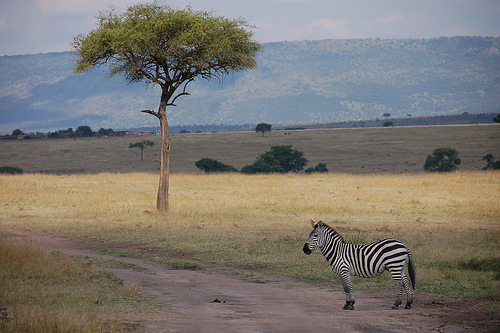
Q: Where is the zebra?
A: Road.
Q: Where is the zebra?
A: Plains.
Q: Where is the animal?
A: Near tree.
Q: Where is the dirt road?
A: Plains.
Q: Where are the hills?
A: Background.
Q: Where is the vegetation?
A: Hills.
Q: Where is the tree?
A: By zebra.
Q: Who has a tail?
A: Zebra.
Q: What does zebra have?
A: Tail.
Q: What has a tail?
A: Zebra.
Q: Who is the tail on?
A: Zebra.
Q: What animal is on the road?
A: Zebra.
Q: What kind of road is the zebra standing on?
A: Dirt road.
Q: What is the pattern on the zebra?
A: Stripes.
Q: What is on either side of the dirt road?
A: Grass.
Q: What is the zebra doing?
A: Standing.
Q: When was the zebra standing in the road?
A: During daylight hours.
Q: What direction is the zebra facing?
A: Left.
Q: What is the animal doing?
A: Standing.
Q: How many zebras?
A: One.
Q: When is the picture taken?
A: Daytime.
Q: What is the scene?
A: A landscape.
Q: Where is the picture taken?
A: On a road.